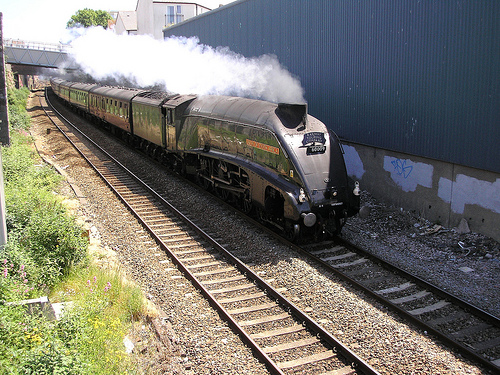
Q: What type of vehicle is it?
A: Train.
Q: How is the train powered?
A: Steam.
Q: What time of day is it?
A: Day time.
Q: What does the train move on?
A: Tracks.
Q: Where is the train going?
A: Route and destination.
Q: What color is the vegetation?
A: Green.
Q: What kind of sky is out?
A: Clear.